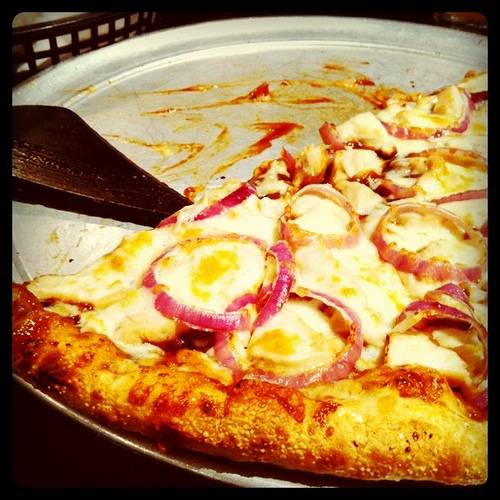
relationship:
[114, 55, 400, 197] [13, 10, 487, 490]
sauce on pan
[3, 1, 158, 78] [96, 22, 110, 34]
basket with hole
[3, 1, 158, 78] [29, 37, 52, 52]
basket with hole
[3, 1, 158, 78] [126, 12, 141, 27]
basket with hole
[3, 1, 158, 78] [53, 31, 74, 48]
basket with hole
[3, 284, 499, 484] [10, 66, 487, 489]
crust of pizza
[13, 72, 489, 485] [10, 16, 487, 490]
cheese left on pan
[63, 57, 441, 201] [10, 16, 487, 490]
sauce left on pan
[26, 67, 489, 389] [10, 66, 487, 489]
cheese on pizza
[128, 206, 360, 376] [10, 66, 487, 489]
onion on pizza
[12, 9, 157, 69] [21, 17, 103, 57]
paper lying in basket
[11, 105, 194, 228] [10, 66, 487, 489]
pizza server of pizza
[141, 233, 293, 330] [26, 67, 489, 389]
onion in cheese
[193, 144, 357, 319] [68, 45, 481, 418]
onions with mozzarella